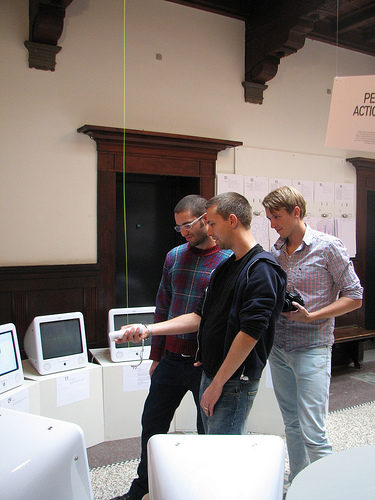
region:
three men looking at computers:
[108, 184, 363, 496]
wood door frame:
[75, 122, 240, 343]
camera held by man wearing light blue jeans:
[281, 285, 311, 321]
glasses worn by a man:
[171, 212, 197, 227]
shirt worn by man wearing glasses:
[150, 242, 231, 355]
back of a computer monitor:
[145, 435, 282, 496]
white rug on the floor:
[90, 397, 371, 495]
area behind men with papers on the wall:
[214, 169, 351, 253]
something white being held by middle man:
[106, 320, 151, 343]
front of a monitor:
[24, 311, 85, 372]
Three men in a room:
[128, 168, 357, 477]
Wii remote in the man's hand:
[108, 321, 154, 366]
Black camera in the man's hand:
[280, 287, 315, 320]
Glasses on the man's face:
[173, 208, 207, 232]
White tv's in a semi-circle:
[5, 289, 285, 494]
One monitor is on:
[1, 335, 34, 386]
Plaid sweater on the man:
[132, 238, 234, 369]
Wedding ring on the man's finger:
[200, 399, 212, 414]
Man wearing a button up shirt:
[258, 180, 337, 463]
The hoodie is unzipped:
[169, 232, 281, 390]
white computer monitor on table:
[34, 308, 93, 373]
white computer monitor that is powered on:
[0, 322, 28, 398]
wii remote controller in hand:
[111, 324, 150, 342]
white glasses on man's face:
[176, 215, 199, 230]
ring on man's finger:
[202, 403, 208, 412]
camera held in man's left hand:
[283, 290, 304, 318]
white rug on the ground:
[340, 407, 374, 452]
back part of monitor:
[148, 434, 292, 497]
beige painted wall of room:
[24, 173, 94, 259]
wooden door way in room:
[84, 131, 238, 181]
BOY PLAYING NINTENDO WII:
[194, 208, 248, 471]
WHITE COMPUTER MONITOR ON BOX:
[111, 422, 259, 497]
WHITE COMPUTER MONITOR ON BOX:
[3, 411, 124, 484]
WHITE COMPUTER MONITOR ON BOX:
[1, 339, 38, 392]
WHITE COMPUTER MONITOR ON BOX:
[30, 307, 84, 357]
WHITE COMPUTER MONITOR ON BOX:
[114, 304, 163, 357]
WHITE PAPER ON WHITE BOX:
[48, 368, 91, 400]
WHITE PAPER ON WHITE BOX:
[4, 390, 33, 411]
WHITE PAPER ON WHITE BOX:
[122, 361, 143, 388]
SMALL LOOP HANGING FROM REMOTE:
[122, 331, 152, 374]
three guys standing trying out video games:
[97, 186, 368, 468]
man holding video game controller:
[93, 322, 166, 390]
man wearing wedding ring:
[185, 376, 221, 440]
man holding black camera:
[274, 280, 319, 324]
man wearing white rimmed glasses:
[162, 206, 222, 243]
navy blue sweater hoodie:
[187, 235, 293, 408]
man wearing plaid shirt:
[245, 204, 371, 370]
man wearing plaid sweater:
[130, 216, 235, 385]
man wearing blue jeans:
[260, 335, 365, 481]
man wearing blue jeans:
[181, 355, 258, 445]